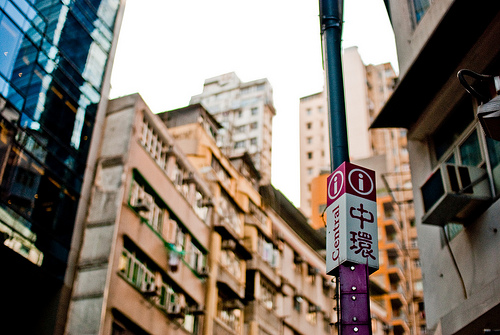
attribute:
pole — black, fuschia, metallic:
[318, 3, 379, 335]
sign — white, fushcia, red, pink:
[327, 161, 378, 270]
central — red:
[328, 206, 344, 264]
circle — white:
[348, 166, 374, 196]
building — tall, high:
[2, 3, 125, 333]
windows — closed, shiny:
[8, 15, 77, 127]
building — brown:
[115, 89, 371, 334]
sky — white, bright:
[108, 1, 415, 213]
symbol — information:
[327, 172, 346, 197]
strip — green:
[124, 184, 216, 285]